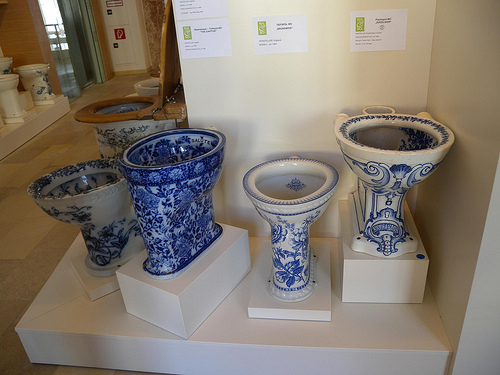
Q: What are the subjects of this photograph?
A: Toilets.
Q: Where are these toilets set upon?
A: Pedestals.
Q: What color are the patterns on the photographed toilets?
A: Blue.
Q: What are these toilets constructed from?
A: Porcelain.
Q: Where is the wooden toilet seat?
A: In the upper left area.